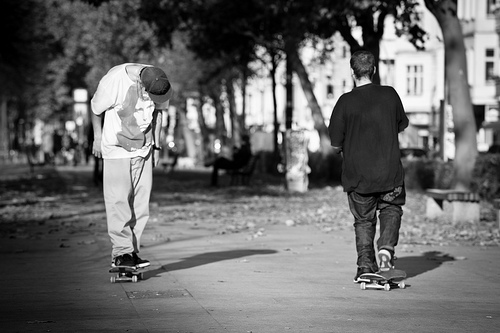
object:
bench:
[422, 187, 482, 226]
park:
[0, 0, 499, 331]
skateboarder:
[327, 49, 412, 283]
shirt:
[327, 82, 410, 194]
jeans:
[345, 181, 407, 273]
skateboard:
[354, 264, 410, 292]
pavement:
[0, 169, 499, 332]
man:
[202, 135, 234, 193]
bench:
[225, 150, 265, 193]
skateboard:
[106, 258, 151, 285]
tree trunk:
[423, 1, 480, 195]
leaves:
[0, 170, 499, 269]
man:
[87, 61, 170, 267]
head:
[137, 66, 176, 106]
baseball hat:
[140, 66, 173, 105]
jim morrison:
[116, 82, 157, 153]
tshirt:
[91, 62, 172, 161]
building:
[440, 0, 496, 154]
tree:
[423, 0, 499, 192]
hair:
[349, 46, 376, 82]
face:
[130, 93, 155, 134]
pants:
[102, 148, 155, 259]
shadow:
[140, 245, 281, 281]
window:
[484, 47, 497, 85]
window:
[405, 64, 423, 99]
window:
[326, 76, 336, 99]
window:
[260, 90, 266, 117]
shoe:
[113, 251, 139, 272]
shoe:
[132, 252, 151, 269]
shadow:
[390, 247, 460, 288]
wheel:
[130, 275, 139, 284]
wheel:
[108, 274, 117, 284]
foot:
[353, 267, 375, 284]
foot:
[111, 252, 139, 270]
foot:
[134, 254, 151, 270]